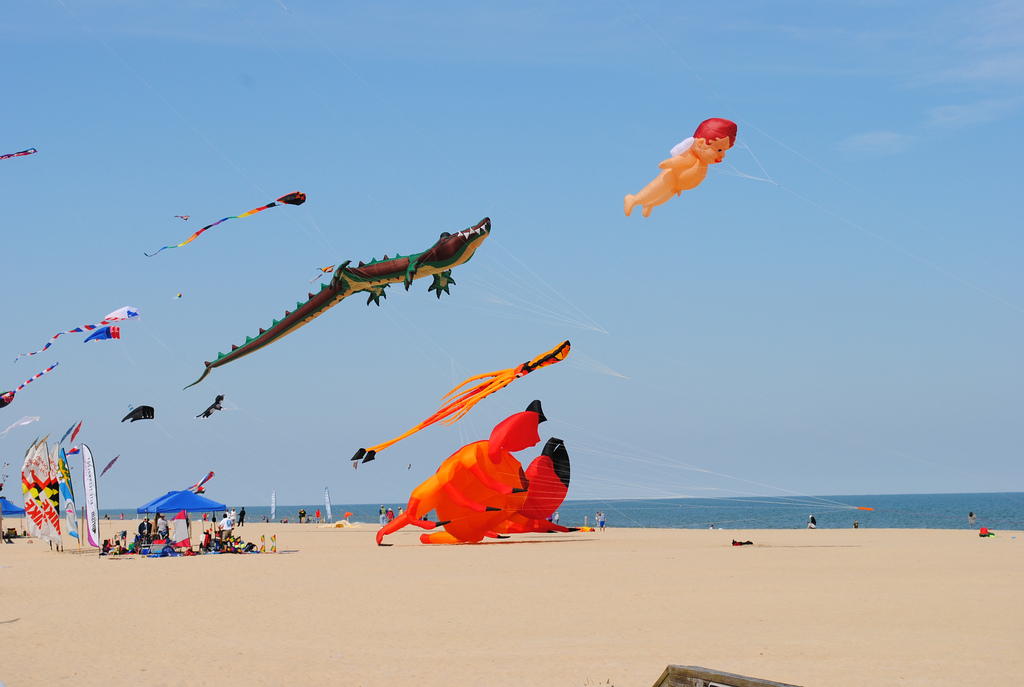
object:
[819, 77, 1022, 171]
clouds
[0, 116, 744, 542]
kites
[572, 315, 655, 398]
clouds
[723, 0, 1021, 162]
clouds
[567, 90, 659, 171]
clouds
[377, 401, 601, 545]
kite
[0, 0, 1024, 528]
sky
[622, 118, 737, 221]
kite